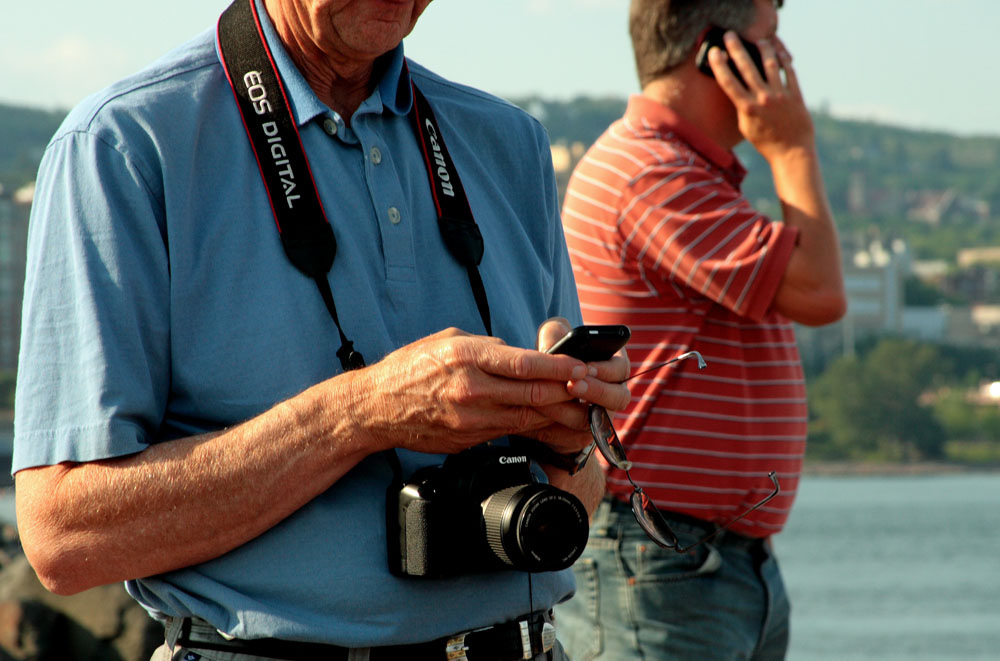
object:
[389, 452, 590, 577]
camera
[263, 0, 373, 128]
neck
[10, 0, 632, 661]
man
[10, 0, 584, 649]
shirt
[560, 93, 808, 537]
shirt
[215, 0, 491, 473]
strap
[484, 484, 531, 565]
lens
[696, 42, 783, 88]
cellphone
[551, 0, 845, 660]
man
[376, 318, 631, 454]
hand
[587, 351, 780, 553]
glasses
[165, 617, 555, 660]
belt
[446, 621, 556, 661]
buckle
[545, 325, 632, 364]
cellphone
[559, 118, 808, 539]
lines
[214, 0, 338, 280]
boarders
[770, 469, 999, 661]
river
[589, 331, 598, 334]
button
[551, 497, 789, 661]
jeans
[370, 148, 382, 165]
button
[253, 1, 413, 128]
collar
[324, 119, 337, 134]
button